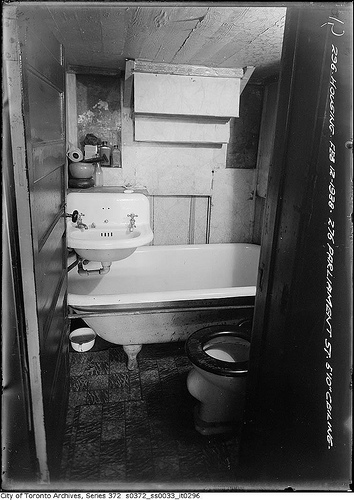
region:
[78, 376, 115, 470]
this is the floor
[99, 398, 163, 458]
the tiles are small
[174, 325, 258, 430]
this is a toilet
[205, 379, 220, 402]
the toilet is white in color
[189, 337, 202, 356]
the seat is black in color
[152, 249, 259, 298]
this is a bath tub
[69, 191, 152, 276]
this is a sink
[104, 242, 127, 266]
the sink is white in color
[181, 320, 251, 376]
black toilet seat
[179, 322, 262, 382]
toilet seat is down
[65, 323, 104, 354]
white bowl on the ground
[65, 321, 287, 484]
tile on the floor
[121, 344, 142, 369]
small leg on the tub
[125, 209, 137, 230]
silver tap on the sink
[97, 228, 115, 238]
four slits in the sink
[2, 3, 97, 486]
the door is open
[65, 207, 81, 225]
handle on the door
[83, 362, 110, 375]
dark tile on floor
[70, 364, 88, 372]
dark tile on floor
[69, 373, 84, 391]
dark tile on floor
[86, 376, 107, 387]
dark tile on floor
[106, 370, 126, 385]
dark tile on floor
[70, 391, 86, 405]
dark tile on floor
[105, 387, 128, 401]
dark tile on floor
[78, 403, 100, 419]
dark tile on floor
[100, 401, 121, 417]
dark tile on floor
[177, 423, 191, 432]
part of a floor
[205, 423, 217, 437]
part of a toilet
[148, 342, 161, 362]
edge of a tab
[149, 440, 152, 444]
part of a floor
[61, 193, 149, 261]
the sink is white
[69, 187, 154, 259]
sink in the bathroom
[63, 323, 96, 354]
white bowl on the floor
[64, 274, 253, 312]
side of the white tub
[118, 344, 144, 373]
white leg of the tub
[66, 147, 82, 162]
toliet paper roll on the shelf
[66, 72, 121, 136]
mirror on the wall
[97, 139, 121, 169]
bottles on the shelf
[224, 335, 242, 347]
black on the toliet bowl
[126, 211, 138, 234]
faucet on the sink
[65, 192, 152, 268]
the sink is white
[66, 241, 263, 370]
the tub is white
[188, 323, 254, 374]
the rim is black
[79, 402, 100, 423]
tile on the floor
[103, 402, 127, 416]
tile on the floor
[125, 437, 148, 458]
tile on the floor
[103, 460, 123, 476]
tile on the floor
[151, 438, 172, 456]
tile on the floor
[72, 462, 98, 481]
tile on the floor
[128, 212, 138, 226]
faucet on the sink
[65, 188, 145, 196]
top of a sink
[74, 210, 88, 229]
the faucet is silver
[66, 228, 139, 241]
basin of the sink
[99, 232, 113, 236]
holes in the sink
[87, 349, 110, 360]
tile on the floor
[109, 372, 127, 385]
tile on the floor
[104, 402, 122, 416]
tile on the floor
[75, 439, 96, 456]
tile on the floor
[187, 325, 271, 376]
a black plastic toilet seat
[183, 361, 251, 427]
base of a toilet